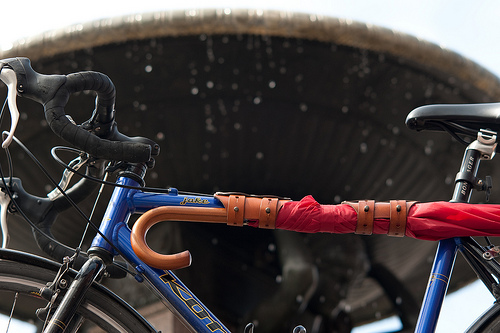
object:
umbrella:
[130, 195, 499, 272]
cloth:
[247, 195, 499, 241]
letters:
[177, 197, 186, 206]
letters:
[153, 270, 193, 300]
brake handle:
[0, 64, 22, 150]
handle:
[0, 55, 162, 281]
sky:
[2, 0, 499, 91]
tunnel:
[0, 8, 499, 332]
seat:
[401, 101, 499, 134]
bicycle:
[0, 56, 498, 332]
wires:
[47, 144, 216, 199]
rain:
[43, 34, 499, 327]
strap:
[384, 198, 410, 237]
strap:
[353, 198, 375, 236]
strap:
[258, 193, 278, 230]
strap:
[224, 194, 245, 228]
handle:
[127, 202, 232, 271]